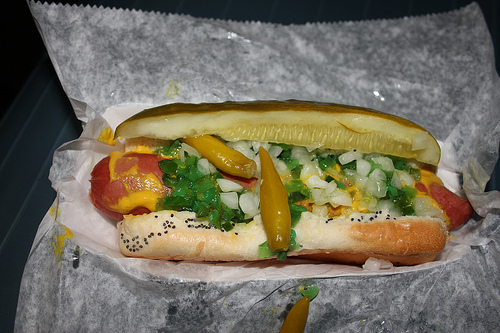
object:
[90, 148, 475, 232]
hotdog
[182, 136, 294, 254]
pickles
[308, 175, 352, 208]
onions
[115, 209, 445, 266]
bun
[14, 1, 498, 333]
paper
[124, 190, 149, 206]
mustard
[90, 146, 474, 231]
wiener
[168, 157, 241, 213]
relish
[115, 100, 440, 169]
pickle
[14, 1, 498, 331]
wrapper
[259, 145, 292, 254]
peppers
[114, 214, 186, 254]
seeds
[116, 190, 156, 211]
cheese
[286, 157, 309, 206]
vegetable